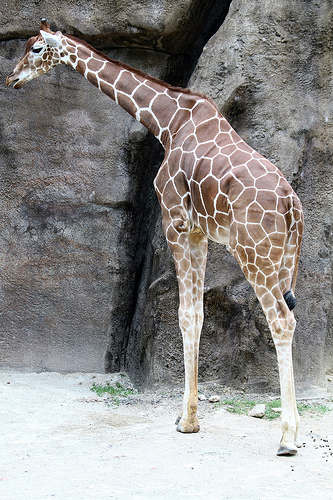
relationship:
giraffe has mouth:
[8, 17, 301, 458] [8, 76, 21, 88]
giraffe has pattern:
[8, 17, 301, 458] [190, 146, 247, 220]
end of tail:
[284, 292, 296, 313] [276, 186, 306, 310]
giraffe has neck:
[8, 17, 301, 458] [60, 30, 206, 146]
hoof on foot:
[278, 443, 296, 457] [277, 417, 301, 458]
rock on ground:
[251, 402, 266, 418] [0, 370, 330, 499]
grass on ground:
[102, 392, 144, 430] [0, 370, 330, 499]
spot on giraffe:
[191, 157, 212, 184] [8, 17, 301, 458]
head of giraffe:
[9, 18, 64, 88] [8, 17, 301, 458]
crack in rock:
[104, 1, 233, 372] [0, 0, 330, 396]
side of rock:
[1, 44, 144, 372] [0, 0, 330, 396]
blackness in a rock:
[156, 1, 232, 89] [0, 0, 330, 396]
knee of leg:
[176, 308, 197, 335] [163, 219, 205, 421]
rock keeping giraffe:
[0, 0, 330, 396] [8, 17, 301, 458]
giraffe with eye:
[8, 17, 301, 458] [31, 46, 43, 53]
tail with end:
[276, 186, 306, 310] [284, 292, 296, 313]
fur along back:
[60, 28, 239, 133] [63, 27, 239, 137]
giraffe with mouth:
[8, 17, 301, 458] [8, 76, 21, 88]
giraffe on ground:
[8, 17, 301, 458] [0, 370, 330, 499]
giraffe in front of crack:
[8, 17, 301, 458] [104, 1, 233, 372]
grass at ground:
[102, 392, 144, 430] [0, 370, 330, 499]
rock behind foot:
[251, 402, 266, 418] [177, 387, 199, 434]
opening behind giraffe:
[223, 85, 252, 134] [8, 17, 301, 458]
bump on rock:
[17, 179, 79, 219] [0, 0, 330, 396]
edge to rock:
[125, 234, 166, 394] [0, 0, 330, 396]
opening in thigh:
[160, 202, 193, 231] [153, 166, 203, 240]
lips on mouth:
[11, 76, 20, 88] [8, 76, 21, 88]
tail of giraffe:
[276, 186, 306, 310] [8, 17, 301, 458]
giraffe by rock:
[8, 17, 301, 458] [0, 0, 330, 396]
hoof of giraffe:
[177, 418, 198, 434] [8, 17, 301, 458]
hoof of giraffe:
[278, 443, 296, 457] [8, 17, 301, 458]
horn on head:
[40, 18, 48, 31] [9, 18, 64, 88]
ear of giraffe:
[37, 27, 53, 37] [8, 17, 301, 458]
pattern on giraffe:
[190, 146, 247, 220] [8, 17, 301, 458]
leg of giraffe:
[163, 219, 205, 421] [8, 17, 301, 458]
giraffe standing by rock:
[8, 17, 301, 458] [0, 0, 330, 396]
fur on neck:
[60, 28, 239, 133] [60, 30, 206, 146]